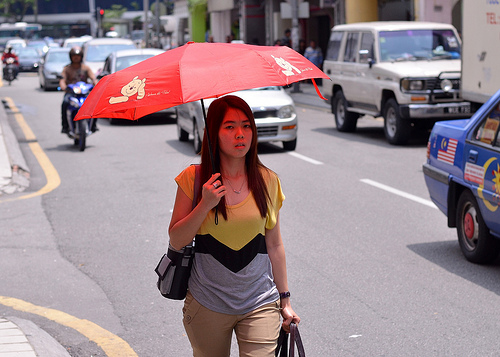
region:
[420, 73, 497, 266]
vehicle driving on road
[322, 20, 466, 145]
vehicle driving on road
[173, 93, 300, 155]
vehicle driving on road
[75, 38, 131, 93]
vehicle driving on road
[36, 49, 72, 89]
vehicle driving on road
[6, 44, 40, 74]
vehicle driving on road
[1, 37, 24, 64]
vehicle driving on road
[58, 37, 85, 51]
vehicle driving on road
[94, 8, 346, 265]
a woman holding an umbrella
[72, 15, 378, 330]
a woman holding a red umbrella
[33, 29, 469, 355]
a woman walking on the road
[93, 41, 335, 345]
a woman walking on the street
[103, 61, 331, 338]
a woman with straight hair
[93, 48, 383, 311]
a red open umbrella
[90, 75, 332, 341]
a woman wearing a shirt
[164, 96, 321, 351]
a woman wearing pants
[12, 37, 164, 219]
a motorcycle on the road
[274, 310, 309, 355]
holding straps to purse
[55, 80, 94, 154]
Blue motorcycle in motion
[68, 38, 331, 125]
big animated red umbrella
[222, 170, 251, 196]
Necklace on the woman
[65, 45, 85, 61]
Helment on the man riding motorcycle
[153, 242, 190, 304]
Small black canteen with phone pocket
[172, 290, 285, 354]
Khaki pants on the woman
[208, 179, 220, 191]
Ring on womans finger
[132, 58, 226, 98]
A red umbrella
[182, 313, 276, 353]
brown pants in the photo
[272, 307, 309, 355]
A handbag in the photo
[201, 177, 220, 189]
A ring on the finger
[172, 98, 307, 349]
a woman in the photo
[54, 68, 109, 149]
A bike in the photo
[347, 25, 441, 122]
A truck in the photo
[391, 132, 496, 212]
A cab in the photo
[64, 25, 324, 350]
woman carrying an umbrella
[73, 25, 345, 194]
umbrella in girl's hand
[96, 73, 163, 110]
character on the umbrella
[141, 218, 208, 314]
bag on the woman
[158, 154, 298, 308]
blouse on the woman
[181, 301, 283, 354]
pants on the woman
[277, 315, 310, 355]
straps in woman's hands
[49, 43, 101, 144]
person on motorized bike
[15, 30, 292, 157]
vehicles on the street